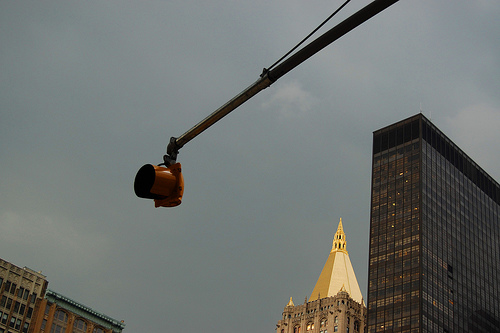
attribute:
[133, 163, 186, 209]
casing — deep orange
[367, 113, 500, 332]
building — large, thin, black, tall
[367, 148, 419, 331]
windows — arched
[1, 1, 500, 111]
sky — dark, cloudy, light gray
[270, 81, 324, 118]
cloud — small, light gray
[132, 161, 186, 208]
light — yellow